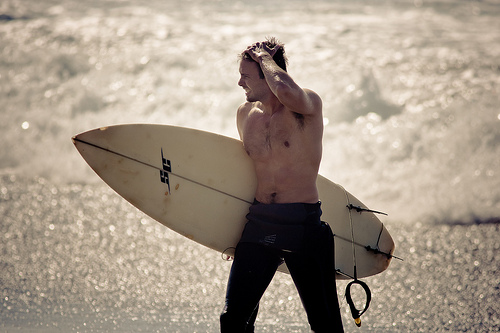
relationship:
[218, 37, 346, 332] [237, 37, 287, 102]
man has head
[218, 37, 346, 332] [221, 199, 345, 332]
man wearing wetsuit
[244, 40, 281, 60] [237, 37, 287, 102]
hand on top of head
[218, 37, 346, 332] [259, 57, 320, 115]
man has arm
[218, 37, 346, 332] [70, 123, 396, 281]
man holding surfboard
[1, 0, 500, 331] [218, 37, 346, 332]
ocean behind man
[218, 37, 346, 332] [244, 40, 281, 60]
man has hand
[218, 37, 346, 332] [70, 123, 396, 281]
man carrying surfboard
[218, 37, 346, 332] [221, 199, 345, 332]
man has wetsuit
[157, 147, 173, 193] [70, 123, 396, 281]
logo printed on surfboard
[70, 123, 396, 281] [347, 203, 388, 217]
surfboard has fin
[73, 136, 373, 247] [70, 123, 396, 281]
line on middle of surfboard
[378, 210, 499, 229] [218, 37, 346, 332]
wave behind man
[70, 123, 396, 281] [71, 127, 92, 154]
surfboard has point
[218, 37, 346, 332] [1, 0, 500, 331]
man walking out of ocean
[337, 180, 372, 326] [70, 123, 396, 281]
rope attached to surfboard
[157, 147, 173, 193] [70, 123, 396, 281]
logo on bottom of surfboard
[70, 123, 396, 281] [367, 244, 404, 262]
surfboard has fin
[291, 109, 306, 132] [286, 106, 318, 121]
hair under armpit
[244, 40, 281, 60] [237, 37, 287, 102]
hand touching head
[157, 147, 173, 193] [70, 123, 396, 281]
logo written on surfboard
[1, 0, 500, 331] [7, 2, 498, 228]
ocean in background